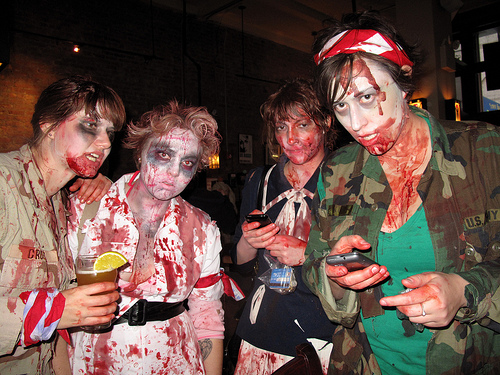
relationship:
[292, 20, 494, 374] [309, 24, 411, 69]
person wearing band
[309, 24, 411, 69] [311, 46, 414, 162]
band on head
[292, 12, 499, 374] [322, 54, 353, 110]
person has hair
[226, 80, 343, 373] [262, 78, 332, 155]
person has hair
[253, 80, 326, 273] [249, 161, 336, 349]
person wearing shirt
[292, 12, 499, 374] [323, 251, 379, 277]
person holding phone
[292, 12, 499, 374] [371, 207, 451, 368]
person wearing shirt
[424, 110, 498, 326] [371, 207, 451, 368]
shirt over shirt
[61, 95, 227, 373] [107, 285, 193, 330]
person wearing belt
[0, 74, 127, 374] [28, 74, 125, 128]
person has hair